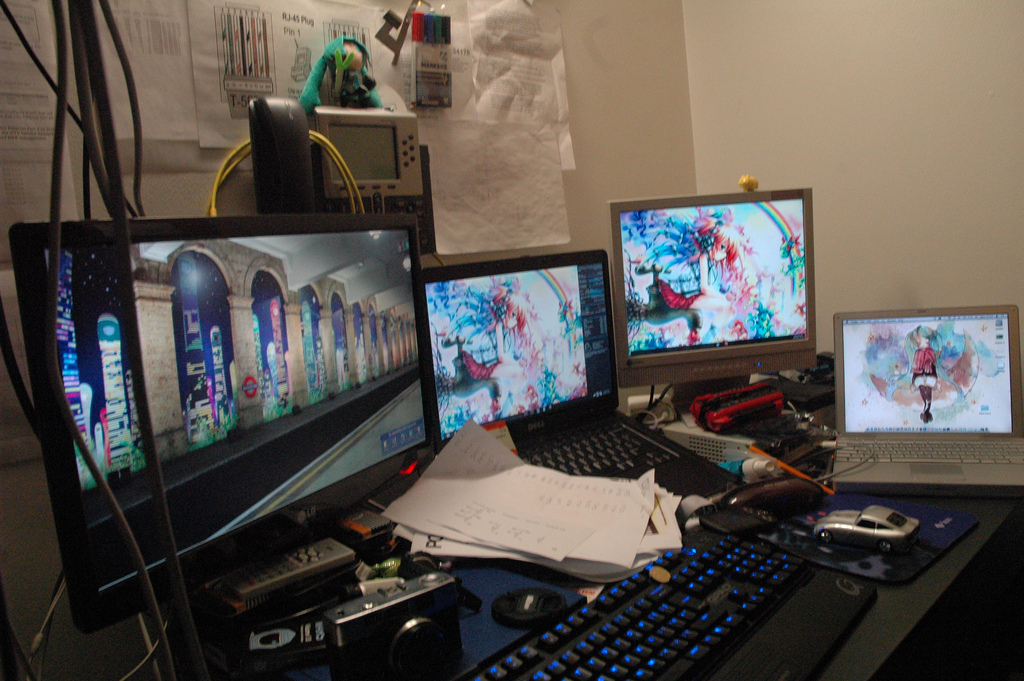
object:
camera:
[325, 571, 464, 680]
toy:
[814, 505, 921, 555]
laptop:
[832, 305, 1024, 495]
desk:
[76, 363, 1024, 681]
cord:
[208, 129, 369, 217]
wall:
[684, 0, 1024, 355]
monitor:
[5, 212, 441, 635]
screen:
[424, 263, 611, 441]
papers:
[381, 416, 682, 573]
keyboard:
[455, 530, 813, 681]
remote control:
[221, 537, 356, 599]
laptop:
[419, 248, 742, 506]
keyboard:
[514, 418, 679, 481]